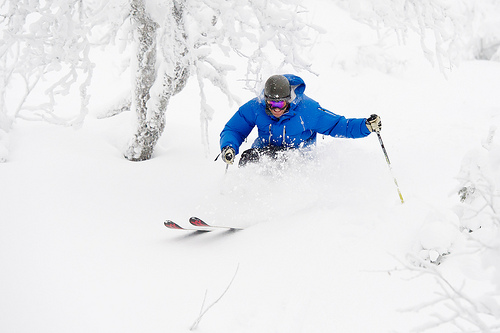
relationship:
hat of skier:
[259, 71, 294, 97] [163, 69, 390, 237]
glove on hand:
[364, 114, 386, 135] [367, 115, 379, 130]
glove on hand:
[217, 146, 241, 166] [225, 151, 238, 164]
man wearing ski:
[219, 74, 382, 168] [187, 214, 242, 233]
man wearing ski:
[219, 74, 382, 168] [164, 218, 206, 234]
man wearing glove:
[219, 74, 382, 168] [223, 147, 263, 164]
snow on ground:
[0, 60, 498, 331] [2, 60, 499, 330]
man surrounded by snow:
[219, 74, 382, 168] [4, 9, 490, 331]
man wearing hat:
[219, 74, 382, 168] [264, 75, 290, 99]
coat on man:
[219, 73, 371, 151] [218, 73, 381, 168]